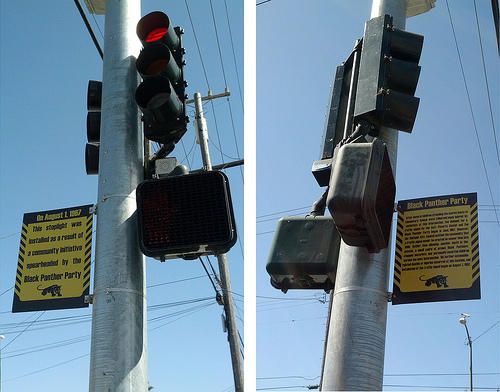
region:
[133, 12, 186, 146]
Black traffic light with red illuminated.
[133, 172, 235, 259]
Square crosswalk indicator pointed at the camera that is not on.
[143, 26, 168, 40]
Red light of the traffic light.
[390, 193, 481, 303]
Black and yellow sign to the far right of another.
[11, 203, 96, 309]
The black and yellow sign with less writing on it than the other.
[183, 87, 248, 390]
A grey power pole leaning severaly to the left.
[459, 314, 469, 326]
White light under the sign with more writing on it.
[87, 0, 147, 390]
Silver pole beside the black light with red illuminated.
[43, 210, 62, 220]
The wod AUGUST on a yellow and black sign with bigger writing.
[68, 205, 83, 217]
The year 1967.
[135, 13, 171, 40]
The light is red.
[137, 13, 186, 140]
The street light is black.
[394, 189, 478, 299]
The sign is yellow and black.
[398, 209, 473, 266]
The writing is black.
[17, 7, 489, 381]
The sky is clear blue.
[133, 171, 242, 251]
Teh light is off.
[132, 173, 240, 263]
The light is black.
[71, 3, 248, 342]
The power lines are in the sky.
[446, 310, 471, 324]
The street lamp is off.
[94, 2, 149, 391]
The pole is silver.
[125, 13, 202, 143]
a traffic light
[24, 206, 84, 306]
a sign on the pole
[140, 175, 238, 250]
a traffic signal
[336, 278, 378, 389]
a metal pole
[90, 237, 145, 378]
a shadow on the pole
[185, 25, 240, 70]
electrical lines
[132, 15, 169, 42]
a red light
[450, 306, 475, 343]
a street light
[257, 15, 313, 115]
the sky is blue and clear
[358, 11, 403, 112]
the side of the street light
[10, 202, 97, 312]
Sign dedicating stop light to Black Panther Party,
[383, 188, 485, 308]
Sign dedicating stop light to Black Panther Party,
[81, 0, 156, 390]
Steel traffic light pole.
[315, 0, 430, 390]
Steel traffic light pole.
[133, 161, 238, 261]
Pedestrian traffic signal stating "Don't Walk."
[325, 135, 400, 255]
Pedestrian traffic signal.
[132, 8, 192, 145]
The traffic light is red.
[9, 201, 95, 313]
On August 1, 1967, This stoplight was installed as a result of a community initiative spearheaded by the Black Panther Party.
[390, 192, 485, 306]
Yellow and black dedication sign.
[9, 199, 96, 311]
Yellow and black dedication sign.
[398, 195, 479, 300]
an unreadable sign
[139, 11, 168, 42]
the red light is on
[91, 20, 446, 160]
some traffic lights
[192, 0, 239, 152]
traffic lights wirings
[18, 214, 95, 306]
a sign with a yellow background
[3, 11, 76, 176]
a blue sky without clouds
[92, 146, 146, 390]
a thick metal pole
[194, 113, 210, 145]
an electrical transformer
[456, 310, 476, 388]
a lamppost at the right side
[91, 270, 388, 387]
two thick metal tube